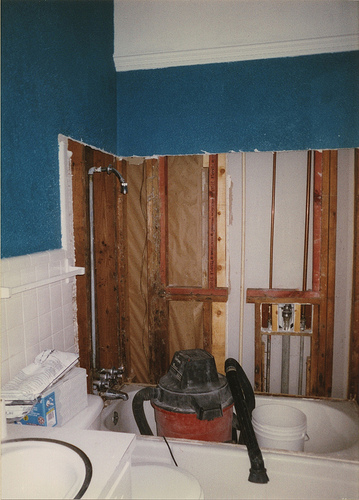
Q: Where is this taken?
A: A bathroom.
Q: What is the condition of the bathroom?
A: Under renovation.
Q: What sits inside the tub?
A: A wet and dry vacuum.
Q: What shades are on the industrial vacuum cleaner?
A: Red and black.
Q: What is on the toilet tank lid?
A: Assorted packages.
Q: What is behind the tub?
A: Wooden molding painted white.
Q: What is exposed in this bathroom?
A: Unfinished wall.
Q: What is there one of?
A: Large wet dry vacuum.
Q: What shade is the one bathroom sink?
A: White.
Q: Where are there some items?
A: Inside white bathtub.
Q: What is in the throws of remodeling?
A: A bathroom.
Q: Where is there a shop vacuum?
A: In a bathtub.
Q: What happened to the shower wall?
A: Been gutted.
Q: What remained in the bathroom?
A: The piping.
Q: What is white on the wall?
A: Ceramic tile.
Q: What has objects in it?
A: Bathroom tub.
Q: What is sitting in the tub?
A: A shopvac.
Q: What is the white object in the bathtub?
A: A bucket.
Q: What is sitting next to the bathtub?
A: A toilet.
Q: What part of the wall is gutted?
A: The bathtub wall.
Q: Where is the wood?
A: On the wall.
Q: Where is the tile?
A: Above the toilet?.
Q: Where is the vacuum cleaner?
A: In the tub.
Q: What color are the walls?
A: Blue.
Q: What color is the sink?
A: White.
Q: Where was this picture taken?
A: The bathroom.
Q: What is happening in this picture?
A: The bathroom is being renovated.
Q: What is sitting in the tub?
A: A wet vac.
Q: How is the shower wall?
A: It is torn up.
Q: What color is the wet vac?
A: Red.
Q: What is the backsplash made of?
A: Ceramic tile.